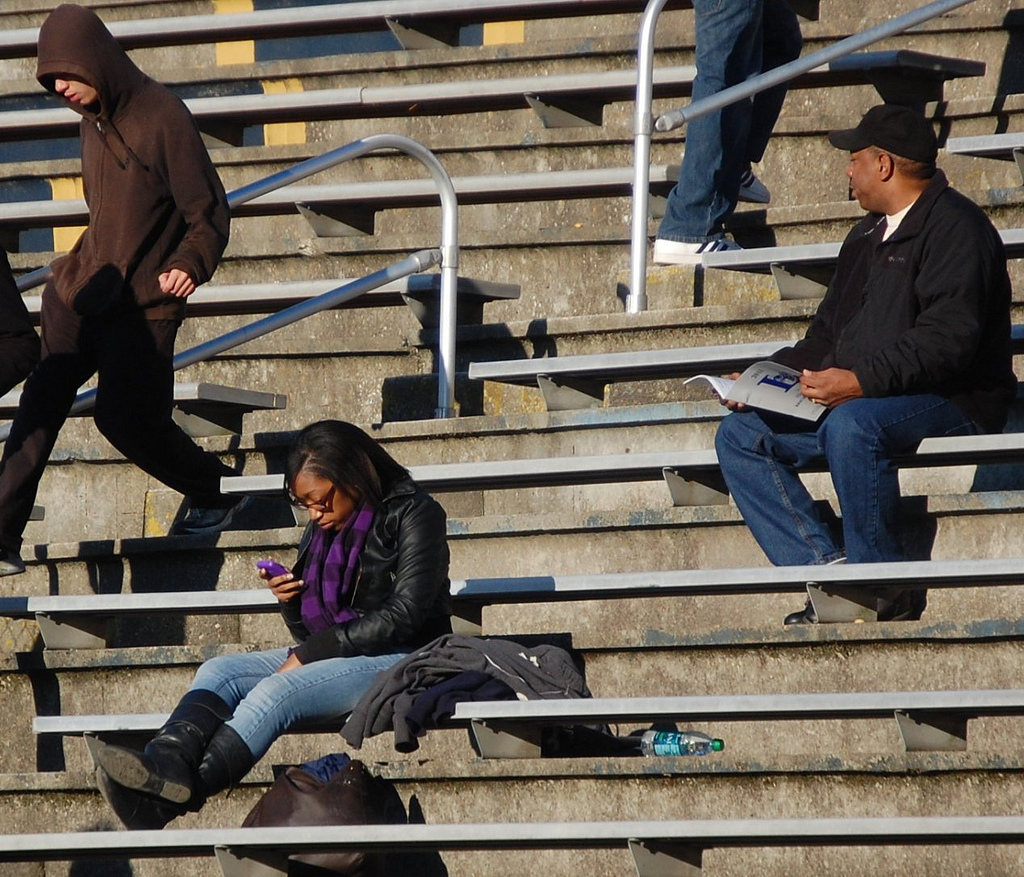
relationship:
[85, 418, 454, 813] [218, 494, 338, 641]
lady looking cellphone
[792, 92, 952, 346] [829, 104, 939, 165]
boy in cap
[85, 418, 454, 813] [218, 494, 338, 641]
lady using cellphone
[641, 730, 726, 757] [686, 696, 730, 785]
bottle on bleacher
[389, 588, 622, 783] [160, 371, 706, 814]
lady holding bag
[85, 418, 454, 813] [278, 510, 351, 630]
lady wearing scraf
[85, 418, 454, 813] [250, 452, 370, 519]
lady wearing glasses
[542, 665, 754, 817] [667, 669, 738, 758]
bottle in ground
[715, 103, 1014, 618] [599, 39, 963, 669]
boy with books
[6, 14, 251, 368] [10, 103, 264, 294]
lady wearing jacket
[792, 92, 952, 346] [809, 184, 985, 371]
boy wearing hoddie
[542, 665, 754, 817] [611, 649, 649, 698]
bottle in ground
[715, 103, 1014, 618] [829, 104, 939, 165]
boy wearing cap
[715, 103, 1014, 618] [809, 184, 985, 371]
boy wearing hoddie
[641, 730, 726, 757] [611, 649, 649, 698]
bottle in ground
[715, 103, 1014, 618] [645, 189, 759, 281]
boy wearing shoes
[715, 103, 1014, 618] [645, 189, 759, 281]
boy wearing sheos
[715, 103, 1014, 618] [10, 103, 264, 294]
boy wearing jacket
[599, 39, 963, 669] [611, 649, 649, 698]
books in ground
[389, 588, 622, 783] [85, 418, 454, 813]
handbag beside lady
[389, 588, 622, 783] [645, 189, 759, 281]
lady wearing shoes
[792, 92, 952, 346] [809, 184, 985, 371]
boy wearing hoddied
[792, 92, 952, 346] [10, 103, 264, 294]
boy wearing jacket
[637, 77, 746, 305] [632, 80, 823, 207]
person claimbing stairs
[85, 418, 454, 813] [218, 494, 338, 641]
lady seeing cellphone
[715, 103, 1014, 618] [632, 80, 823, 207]
boy wearing pant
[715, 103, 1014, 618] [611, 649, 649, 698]
boy in ground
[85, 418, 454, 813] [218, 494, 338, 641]
lady playing cellphone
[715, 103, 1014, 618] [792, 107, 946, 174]
boy wearing cap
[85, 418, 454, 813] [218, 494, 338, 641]
lady looking at cellphone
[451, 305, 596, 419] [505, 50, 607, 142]
shadow on top of stairs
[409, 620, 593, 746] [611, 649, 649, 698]
handbag on ground